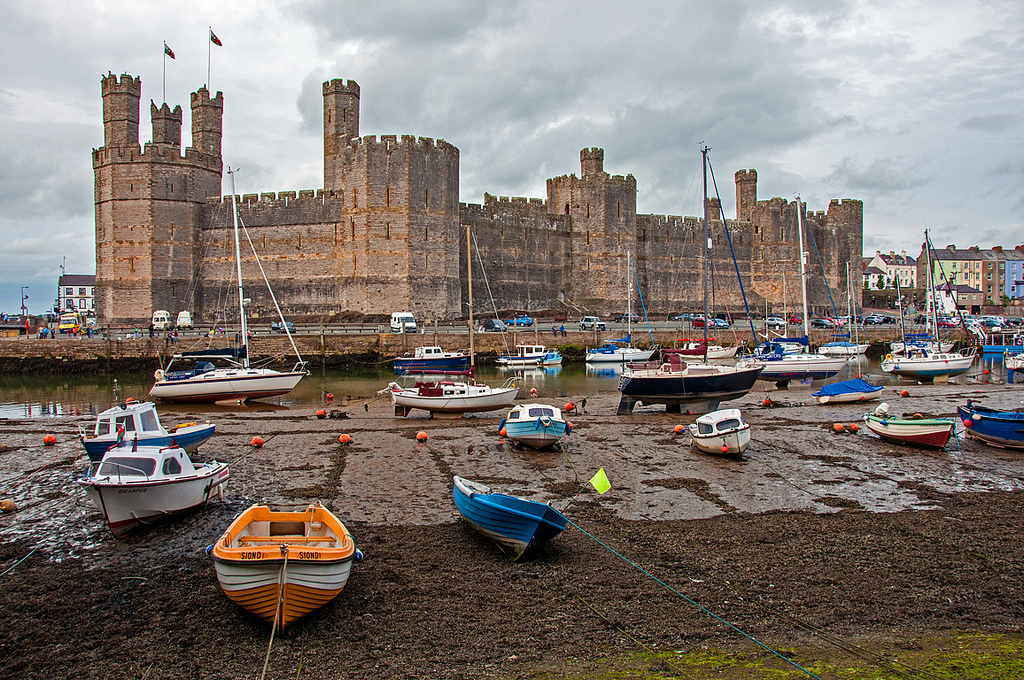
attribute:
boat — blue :
[440, 459, 584, 589]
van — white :
[389, 307, 435, 336]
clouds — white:
[13, 12, 1016, 167]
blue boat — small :
[454, 466, 575, 565]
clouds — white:
[535, 19, 979, 163]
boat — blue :
[445, 462, 578, 555]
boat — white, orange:
[210, 495, 370, 636]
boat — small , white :
[686, 408, 753, 456]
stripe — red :
[690, 422, 745, 438]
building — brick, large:
[89, 67, 869, 338]